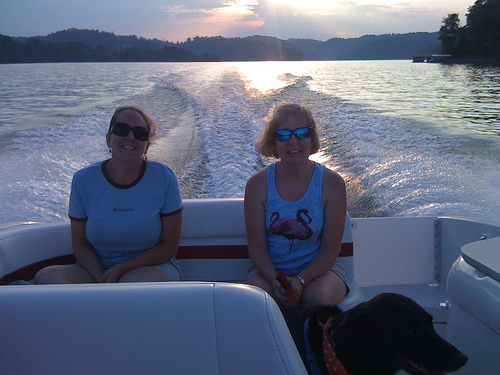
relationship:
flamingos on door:
[264, 205, 315, 254] [352, 216, 437, 287]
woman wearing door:
[244, 101, 351, 308] [352, 216, 437, 287]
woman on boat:
[244, 101, 351, 308] [1, 195, 496, 370]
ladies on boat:
[34, 104, 183, 283] [1, 195, 496, 370]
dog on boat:
[282, 292, 469, 374] [1, 195, 496, 370]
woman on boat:
[244, 101, 351, 308] [376, 220, 490, 349]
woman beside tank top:
[244, 101, 351, 308] [266, 160, 329, 267]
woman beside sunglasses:
[244, 101, 351, 308] [112, 121, 314, 138]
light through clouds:
[150, 0, 358, 38] [3, 3, 469, 40]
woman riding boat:
[244, 101, 351, 308] [1, 195, 496, 370]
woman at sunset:
[244, 101, 351, 308] [154, 1, 267, 36]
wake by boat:
[372, 114, 499, 215] [26, 220, 478, 374]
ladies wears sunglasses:
[34, 104, 183, 283] [112, 121, 314, 138]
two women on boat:
[35, 102, 351, 309] [1, 195, 496, 370]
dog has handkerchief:
[282, 292, 469, 374] [318, 315, 351, 374]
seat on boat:
[6, 272, 311, 370] [1, 195, 496, 370]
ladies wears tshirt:
[34, 104, 183, 283] [67, 164, 182, 263]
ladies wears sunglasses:
[34, 104, 183, 283] [108, 120, 148, 141]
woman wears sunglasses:
[244, 101, 351, 308] [272, 127, 310, 140]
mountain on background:
[284, 28, 447, 61] [1, 13, 497, 69]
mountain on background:
[179, 32, 299, 62] [1, 13, 497, 69]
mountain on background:
[0, 31, 205, 66] [1, 13, 497, 69]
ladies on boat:
[32, 75, 334, 281] [1, 195, 496, 370]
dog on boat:
[307, 279, 487, 366] [1, 195, 496, 370]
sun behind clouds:
[151, 4, 261, 39] [220, 0, 367, 51]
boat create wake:
[1, 195, 496, 370] [140, 53, 258, 180]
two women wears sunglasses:
[35, 102, 351, 309] [272, 127, 310, 140]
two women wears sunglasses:
[35, 105, 182, 284] [108, 120, 148, 141]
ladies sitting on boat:
[34, 104, 183, 283] [1, 195, 496, 370]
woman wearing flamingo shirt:
[248, 95, 358, 306] [261, 154, 327, 274]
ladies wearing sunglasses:
[34, 104, 183, 283] [96, 115, 311, 137]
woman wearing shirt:
[244, 101, 351, 308] [258, 154, 329, 283]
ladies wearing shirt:
[34, 104, 183, 283] [64, 150, 184, 268]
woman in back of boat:
[244, 101, 351, 308] [1, 195, 496, 370]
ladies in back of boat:
[34, 104, 183, 283] [1, 195, 496, 370]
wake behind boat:
[157, 82, 242, 162] [1, 195, 496, 370]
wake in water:
[157, 82, 242, 162] [0, 53, 498, 230]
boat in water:
[1, 195, 496, 370] [0, 53, 498, 230]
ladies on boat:
[34, 104, 183, 283] [9, 200, 490, 360]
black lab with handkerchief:
[277, 291, 474, 373] [322, 303, 345, 364]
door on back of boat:
[352, 214, 437, 286] [1, 195, 496, 370]